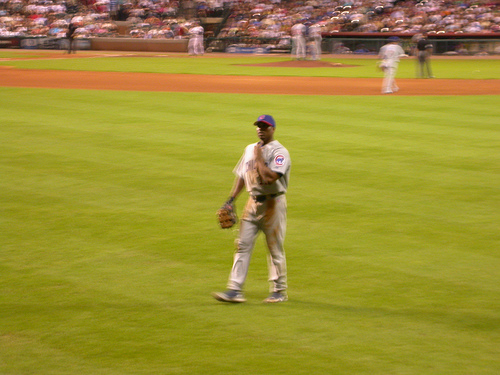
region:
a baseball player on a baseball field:
[217, 111, 292, 306]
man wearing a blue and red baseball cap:
[253, 113, 275, 128]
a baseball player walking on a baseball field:
[378, 36, 409, 95]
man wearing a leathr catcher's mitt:
[216, 196, 238, 228]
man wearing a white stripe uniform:
[230, 139, 291, 294]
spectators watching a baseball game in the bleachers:
[2, 2, 498, 44]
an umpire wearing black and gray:
[413, 32, 433, 79]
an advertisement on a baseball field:
[224, 44, 269, 55]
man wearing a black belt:
[248, 190, 284, 202]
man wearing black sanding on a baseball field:
[66, 22, 78, 52]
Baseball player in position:
[215, 112, 297, 312]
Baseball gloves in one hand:
[215, 196, 241, 231]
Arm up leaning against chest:
[253, 138, 288, 185]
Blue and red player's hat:
[251, 112, 281, 125]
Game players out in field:
[62, 20, 444, 97]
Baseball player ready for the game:
[214, 112, 298, 303]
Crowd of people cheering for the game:
[0, 0, 496, 58]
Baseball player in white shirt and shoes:
[214, 108, 303, 308]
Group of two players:
[376, 30, 447, 95]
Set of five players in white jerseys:
[178, 20, 407, 310]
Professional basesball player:
[211, 105, 303, 305]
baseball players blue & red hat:
[251, 111, 279, 130]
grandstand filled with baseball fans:
[2, 0, 497, 63]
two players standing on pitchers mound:
[228, 20, 369, 73]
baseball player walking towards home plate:
[302, 13, 455, 127]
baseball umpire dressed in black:
[396, 23, 450, 91]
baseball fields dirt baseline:
[4, 50, 498, 124]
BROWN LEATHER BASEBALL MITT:
[217, 196, 239, 228]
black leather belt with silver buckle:
[245, 185, 287, 205]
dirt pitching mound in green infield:
[233, 53, 364, 77]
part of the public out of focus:
[328, 0, 496, 37]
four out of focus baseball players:
[183, 21, 403, 96]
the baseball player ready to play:
[206, 115, 301, 304]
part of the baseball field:
[0, 59, 222, 370]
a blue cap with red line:
[253, 113, 279, 129]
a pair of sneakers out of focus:
[210, 287, 293, 305]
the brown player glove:
[217, 197, 239, 232]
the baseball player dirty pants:
[236, 194, 288, 287]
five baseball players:
[182, 17, 404, 305]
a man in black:
[63, 23, 78, 54]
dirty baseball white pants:
[213, 194, 305, 307]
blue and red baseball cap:
[252, 109, 284, 134]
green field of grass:
[328, 95, 473, 316]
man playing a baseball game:
[189, 99, 321, 322]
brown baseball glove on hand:
[209, 191, 246, 241]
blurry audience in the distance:
[353, 6, 476, 34]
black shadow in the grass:
[298, 283, 498, 346]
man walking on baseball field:
[372, 28, 426, 115]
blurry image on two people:
[285, 19, 330, 65]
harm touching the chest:
[244, 134, 289, 189]